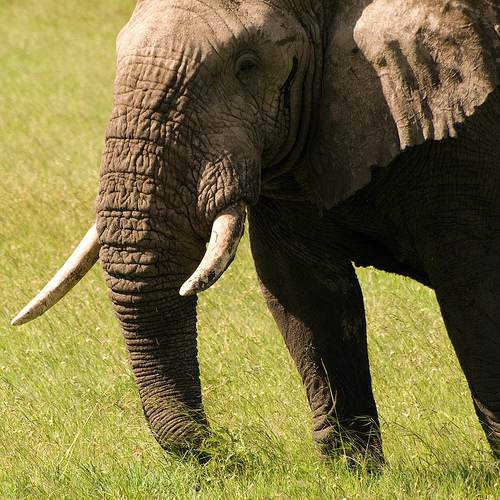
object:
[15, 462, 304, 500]
grass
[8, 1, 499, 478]
elephant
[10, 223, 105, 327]
ivory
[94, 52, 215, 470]
nose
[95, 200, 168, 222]
wrinkles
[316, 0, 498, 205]
ears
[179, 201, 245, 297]
tusk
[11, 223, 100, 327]
tusk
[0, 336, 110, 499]
field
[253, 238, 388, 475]
legs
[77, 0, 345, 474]
front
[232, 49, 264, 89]
eye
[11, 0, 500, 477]
rest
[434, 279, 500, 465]
arm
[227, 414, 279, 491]
patch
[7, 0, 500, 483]
standing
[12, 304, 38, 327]
tip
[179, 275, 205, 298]
tip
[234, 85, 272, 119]
wrinkles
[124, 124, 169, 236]
skin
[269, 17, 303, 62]
mud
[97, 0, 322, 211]
face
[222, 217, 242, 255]
mud